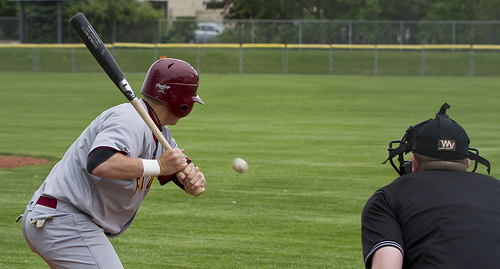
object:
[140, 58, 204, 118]
helmet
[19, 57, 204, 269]
batter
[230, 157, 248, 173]
ball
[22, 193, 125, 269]
pants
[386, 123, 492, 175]
mask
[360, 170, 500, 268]
shirt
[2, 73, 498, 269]
field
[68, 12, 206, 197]
bat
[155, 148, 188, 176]
hand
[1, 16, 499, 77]
fence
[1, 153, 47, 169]
mound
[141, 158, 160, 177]
sweat band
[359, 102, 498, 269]
umpire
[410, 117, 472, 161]
hat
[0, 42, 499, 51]
top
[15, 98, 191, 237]
uniform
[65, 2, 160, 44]
tree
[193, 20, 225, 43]
car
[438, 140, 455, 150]
wv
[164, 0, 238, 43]
building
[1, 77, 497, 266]
grass